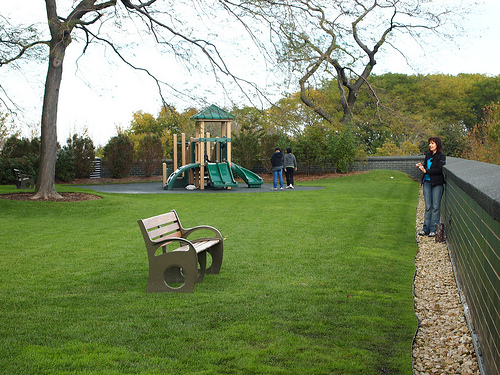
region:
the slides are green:
[166, 161, 265, 189]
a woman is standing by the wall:
[414, 136, 447, 236]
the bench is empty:
[135, 208, 224, 294]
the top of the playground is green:
[188, 104, 236, 120]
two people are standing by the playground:
[268, 144, 300, 190]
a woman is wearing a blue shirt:
[422, 156, 445, 183]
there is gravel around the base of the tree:
[0, 190, 105, 205]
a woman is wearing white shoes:
[284, 146, 299, 189]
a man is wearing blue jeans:
[269, 146, 285, 191]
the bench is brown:
[135, 208, 224, 295]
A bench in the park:
[139, 212, 239, 294]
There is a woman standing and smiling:
[420, 135, 443, 245]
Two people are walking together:
[266, 142, 323, 190]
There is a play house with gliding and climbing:
[156, 96, 268, 190]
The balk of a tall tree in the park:
[41, 0, 61, 198]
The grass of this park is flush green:
[245, 287, 355, 359]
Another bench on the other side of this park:
[7, 161, 36, 193]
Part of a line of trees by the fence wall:
[299, 117, 363, 182]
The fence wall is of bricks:
[468, 217, 491, 314]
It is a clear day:
[78, 77, 121, 120]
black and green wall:
[456, 163, 497, 335]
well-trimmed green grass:
[256, 214, 371, 339]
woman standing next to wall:
[406, 125, 455, 238]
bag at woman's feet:
[411, 210, 451, 246]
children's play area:
[155, 95, 261, 190]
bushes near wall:
[5, 120, 375, 175]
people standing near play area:
[201, 125, 301, 191]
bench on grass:
[113, 195, 238, 300]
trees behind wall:
[286, 68, 498, 173]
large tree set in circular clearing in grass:
[7, 0, 145, 210]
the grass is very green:
[260, 196, 330, 306]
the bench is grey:
[135, 210, 230, 286]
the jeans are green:
[422, 183, 444, 236]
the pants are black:
[278, 167, 300, 181]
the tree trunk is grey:
[41, 131, 59, 184]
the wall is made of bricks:
[381, 157, 414, 169]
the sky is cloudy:
[103, 62, 202, 96]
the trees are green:
[393, 82, 483, 109]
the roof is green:
[201, 105, 230, 117]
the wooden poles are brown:
[172, 132, 217, 161]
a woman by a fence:
[358, 132, 466, 244]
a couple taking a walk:
[265, 125, 310, 205]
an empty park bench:
[116, 194, 253, 302]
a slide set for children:
[156, 105, 272, 196]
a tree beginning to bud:
[2, 0, 284, 227]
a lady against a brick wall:
[415, 131, 498, 327]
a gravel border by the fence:
[394, 223, 479, 370]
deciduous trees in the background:
[64, 60, 497, 161]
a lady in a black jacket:
[409, 115, 454, 241]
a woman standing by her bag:
[389, 122, 451, 248]